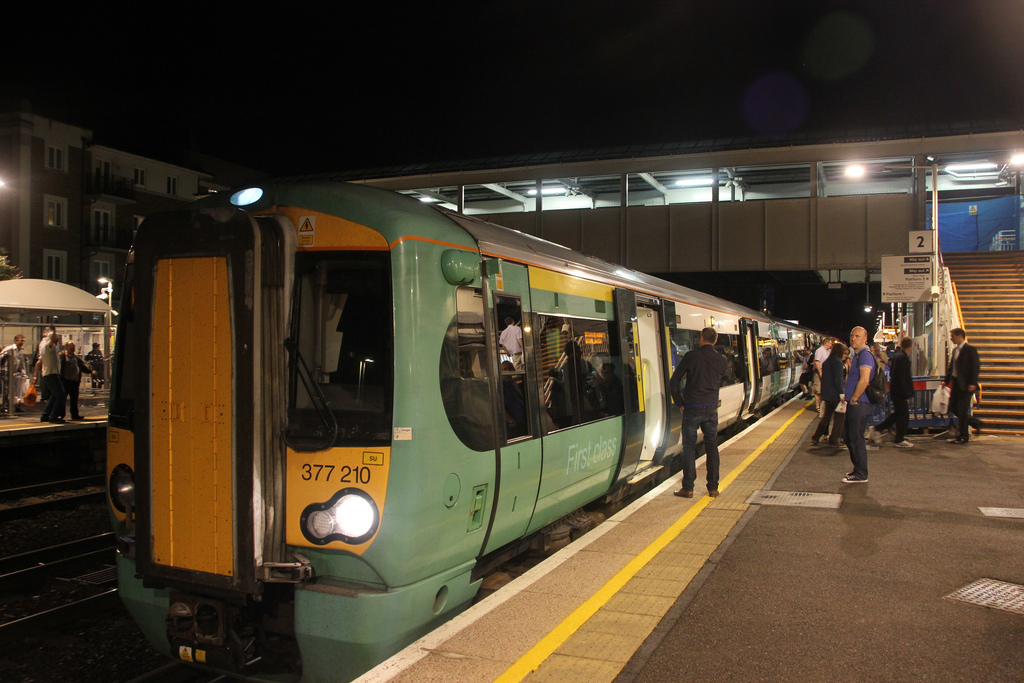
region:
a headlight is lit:
[287, 476, 385, 554]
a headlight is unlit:
[89, 454, 154, 537]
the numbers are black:
[297, 450, 380, 489]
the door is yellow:
[138, 236, 253, 601]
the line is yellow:
[446, 520, 571, 619]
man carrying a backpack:
[827, 309, 900, 497]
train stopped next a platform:
[63, 140, 879, 681]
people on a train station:
[637, 265, 998, 510]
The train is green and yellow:
[93, 136, 972, 628]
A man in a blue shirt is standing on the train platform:
[807, 282, 948, 576]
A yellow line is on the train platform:
[472, 225, 891, 672]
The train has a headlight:
[196, 369, 490, 620]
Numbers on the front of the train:
[229, 399, 461, 608]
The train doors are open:
[554, 220, 792, 525]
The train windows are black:
[375, 225, 854, 507]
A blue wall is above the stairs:
[909, 190, 1021, 425]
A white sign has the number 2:
[886, 208, 966, 292]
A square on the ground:
[737, 424, 918, 622]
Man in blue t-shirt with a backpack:
[842, 325, 891, 484]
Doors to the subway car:
[637, 303, 667, 478]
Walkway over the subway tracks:
[327, 132, 1021, 265]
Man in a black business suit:
[946, 328, 976, 443]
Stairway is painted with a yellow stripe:
[940, 241, 1021, 429]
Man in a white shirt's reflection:
[495, 303, 524, 412]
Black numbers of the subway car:
[299, 459, 373, 486]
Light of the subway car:
[304, 487, 377, 541]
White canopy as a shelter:
[4, 277, 112, 315]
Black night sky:
[5, 4, 1021, 169]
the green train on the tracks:
[105, 180, 827, 672]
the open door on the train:
[611, 286, 681, 486]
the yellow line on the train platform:
[494, 391, 815, 679]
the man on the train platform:
[840, 321, 886, 484]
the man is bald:
[838, 325, 871, 484]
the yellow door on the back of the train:
[153, 253, 230, 571]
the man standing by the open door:
[665, 319, 733, 498]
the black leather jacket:
[666, 343, 731, 408]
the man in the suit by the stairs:
[946, 324, 989, 445]